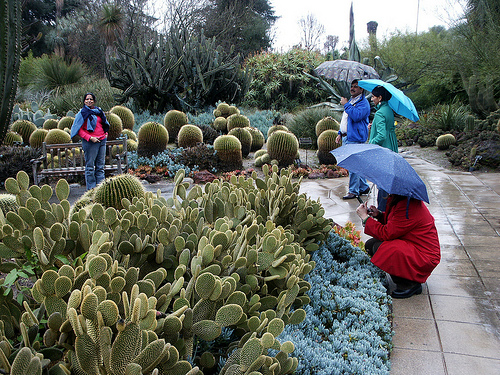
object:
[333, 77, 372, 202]
man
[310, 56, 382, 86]
umbrella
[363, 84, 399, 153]
woman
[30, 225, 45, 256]
plants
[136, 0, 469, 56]
sky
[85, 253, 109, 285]
catus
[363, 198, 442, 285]
coat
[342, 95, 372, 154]
coat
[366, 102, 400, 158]
coat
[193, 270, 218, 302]
catus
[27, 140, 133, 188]
bench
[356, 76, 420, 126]
umbrella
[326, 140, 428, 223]
umbrella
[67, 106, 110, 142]
coat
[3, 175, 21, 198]
cactus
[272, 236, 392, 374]
flowers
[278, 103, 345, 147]
bush